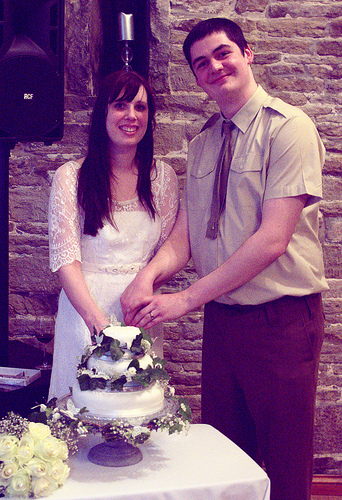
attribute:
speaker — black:
[0, 2, 65, 146]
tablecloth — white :
[70, 431, 265, 497]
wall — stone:
[6, 1, 340, 476]